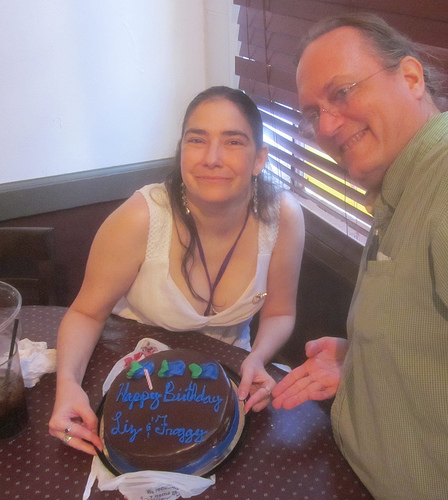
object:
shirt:
[330, 111, 448, 500]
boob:
[211, 271, 267, 323]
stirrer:
[6, 318, 19, 383]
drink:
[0, 298, 29, 438]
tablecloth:
[0, 305, 380, 500]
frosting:
[105, 379, 224, 450]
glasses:
[297, 64, 396, 140]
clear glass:
[0, 281, 28, 436]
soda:
[0, 375, 38, 437]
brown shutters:
[234, 1, 371, 249]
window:
[233, 0, 448, 247]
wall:
[0, 0, 238, 189]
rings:
[64, 421, 75, 434]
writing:
[111, 381, 222, 443]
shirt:
[111, 182, 281, 352]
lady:
[47, 85, 305, 457]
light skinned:
[108, 220, 142, 276]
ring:
[63, 436, 73, 444]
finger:
[49, 416, 103, 452]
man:
[270, 12, 448, 500]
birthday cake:
[102, 349, 240, 477]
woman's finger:
[74, 393, 101, 436]